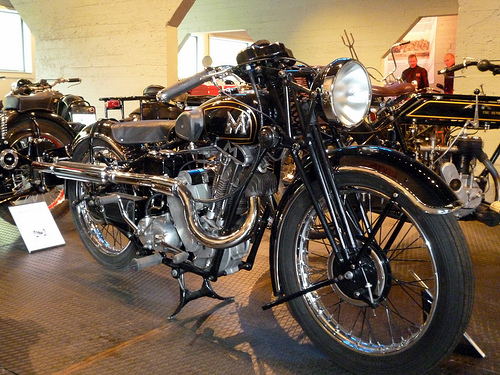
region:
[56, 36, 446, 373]
the motorcycle on display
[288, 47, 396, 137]
the headlight on the motorcycle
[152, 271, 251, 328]
the kickstand under the motorcycle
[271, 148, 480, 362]
the front tire of the motorcycle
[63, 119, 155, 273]
the rear tire of the motorcycle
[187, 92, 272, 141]
the fuel tank on the motorcycle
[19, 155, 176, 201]
the muffler of the motorcycle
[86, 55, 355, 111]
the handle bar of the motorcycle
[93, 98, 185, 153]
the seat of the motorcycle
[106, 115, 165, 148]
the seat is leather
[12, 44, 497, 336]
motorcycles that are inside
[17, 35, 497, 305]
motorcycles in a building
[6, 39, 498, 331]
bikes are inside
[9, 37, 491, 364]
bikes inside a building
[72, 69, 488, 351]
motorcycles on display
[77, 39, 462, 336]
a black bike on display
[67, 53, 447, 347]
a black motorcycle on display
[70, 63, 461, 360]
a black bike inside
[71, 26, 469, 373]
a black motorcycle inside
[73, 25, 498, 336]
a building with motorcycles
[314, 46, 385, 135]
round silver cycle headlight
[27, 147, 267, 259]
long silver exhaust pipe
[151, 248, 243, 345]
black metal kick stand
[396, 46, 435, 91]
man in black looking at cycles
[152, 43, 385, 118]
low slung cycle handlebars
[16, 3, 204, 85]
white stone partition wall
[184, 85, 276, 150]
black and gold gas tank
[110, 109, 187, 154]
flat leather padded seat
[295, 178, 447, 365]
silver metal cycle tire spokes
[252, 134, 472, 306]
black and silver cycle tire fender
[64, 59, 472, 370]
shiny black and chrome motorcycle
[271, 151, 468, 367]
tall thin black tire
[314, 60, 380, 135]
large round headlight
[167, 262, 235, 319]
curved black kickstand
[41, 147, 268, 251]
chrome bar along the side of a bike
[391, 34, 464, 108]
two men in black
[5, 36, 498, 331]
room full of motorcycles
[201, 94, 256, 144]
the letter m on the side of a bike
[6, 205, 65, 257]
white object beside a bike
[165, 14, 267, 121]
wide arched doorway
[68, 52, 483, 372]
The motorcycle is black.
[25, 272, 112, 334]
The ground is gray.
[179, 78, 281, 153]
The gas tank is black.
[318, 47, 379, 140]
The bike has a large headlight.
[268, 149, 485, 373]
The tire is black.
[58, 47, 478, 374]
The bike is clean.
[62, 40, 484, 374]
The bike is glossy.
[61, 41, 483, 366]
The bike is not being used.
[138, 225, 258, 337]
The bike is propped up.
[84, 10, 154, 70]
The wall is white.